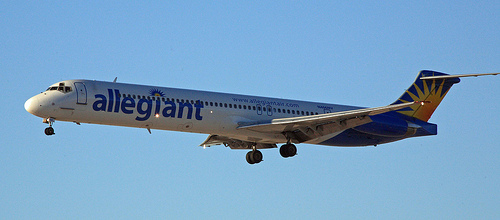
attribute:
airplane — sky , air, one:
[22, 27, 484, 201]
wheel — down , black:
[204, 145, 303, 168]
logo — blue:
[88, 74, 199, 117]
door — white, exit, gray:
[76, 77, 95, 105]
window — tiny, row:
[65, 88, 69, 90]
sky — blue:
[171, 31, 244, 58]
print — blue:
[79, 86, 214, 123]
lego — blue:
[380, 77, 449, 138]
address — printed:
[213, 91, 321, 110]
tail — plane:
[350, 59, 490, 163]